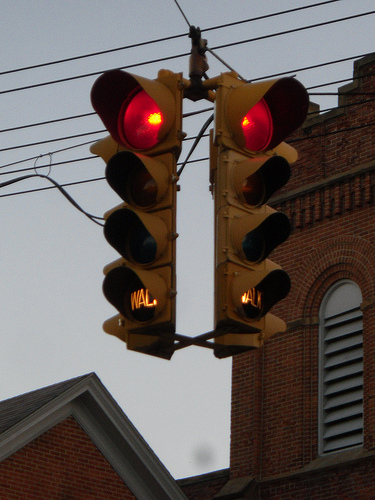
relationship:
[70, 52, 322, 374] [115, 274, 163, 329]
traffic lights painted yellow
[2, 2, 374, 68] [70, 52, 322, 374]
wires over traffic lights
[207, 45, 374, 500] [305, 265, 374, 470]
building has arched windows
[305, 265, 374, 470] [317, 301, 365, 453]
slats pointing downwards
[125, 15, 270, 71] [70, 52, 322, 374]
support attached to signals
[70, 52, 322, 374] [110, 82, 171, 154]
street signal has red light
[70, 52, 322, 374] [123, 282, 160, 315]
street signal has yellow words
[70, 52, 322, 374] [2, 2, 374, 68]
signal hangs from black lines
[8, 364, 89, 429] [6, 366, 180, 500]
roof of building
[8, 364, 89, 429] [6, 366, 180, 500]
slats on building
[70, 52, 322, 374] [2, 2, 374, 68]
traffic lights are hanging from power lines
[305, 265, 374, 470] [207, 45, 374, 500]
window on brick building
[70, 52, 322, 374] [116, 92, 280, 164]
traffic light showing red